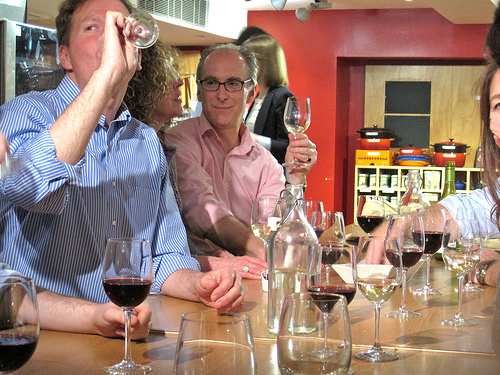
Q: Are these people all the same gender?
A: No, they are both male and female.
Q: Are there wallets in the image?
A: No, there are no wallets.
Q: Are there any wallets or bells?
A: No, there are no wallets or bells.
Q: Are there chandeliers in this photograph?
A: No, there are no chandeliers.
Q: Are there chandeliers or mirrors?
A: No, there are no chandeliers or mirrors.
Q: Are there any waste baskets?
A: No, there are no waste baskets.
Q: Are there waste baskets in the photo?
A: No, there are no waste baskets.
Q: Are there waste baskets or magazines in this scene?
A: No, there are no waste baskets or magazines.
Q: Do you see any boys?
A: No, there are no boys.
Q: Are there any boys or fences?
A: No, there are no boys or fences.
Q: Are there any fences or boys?
A: No, there are no boys or fences.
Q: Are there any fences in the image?
A: No, there are no fences.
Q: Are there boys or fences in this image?
A: No, there are no fences or boys.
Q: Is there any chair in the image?
A: No, there are no chairs.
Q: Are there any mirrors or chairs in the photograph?
A: No, there are no chairs or mirrors.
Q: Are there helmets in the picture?
A: No, there are no helmets.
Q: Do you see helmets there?
A: No, there are no helmets.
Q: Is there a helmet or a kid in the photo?
A: No, there are no helmets or children.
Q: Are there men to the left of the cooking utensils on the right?
A: Yes, there is a man to the left of the cooking utensils.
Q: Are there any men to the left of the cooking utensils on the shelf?
A: Yes, there is a man to the left of the cooking utensils.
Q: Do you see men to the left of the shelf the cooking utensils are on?
A: Yes, there is a man to the left of the shelf.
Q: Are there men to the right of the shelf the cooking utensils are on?
A: No, the man is to the left of the shelf.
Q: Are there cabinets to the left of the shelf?
A: No, there is a man to the left of the shelf.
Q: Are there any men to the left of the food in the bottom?
A: Yes, there is a man to the left of the food.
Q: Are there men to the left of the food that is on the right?
A: Yes, there is a man to the left of the food.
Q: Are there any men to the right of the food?
A: No, the man is to the left of the food.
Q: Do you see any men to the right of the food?
A: No, the man is to the left of the food.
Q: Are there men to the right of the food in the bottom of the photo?
A: No, the man is to the left of the food.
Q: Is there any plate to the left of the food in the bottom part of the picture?
A: No, there is a man to the left of the food.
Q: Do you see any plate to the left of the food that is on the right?
A: No, there is a man to the left of the food.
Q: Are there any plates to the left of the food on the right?
A: No, there is a man to the left of the food.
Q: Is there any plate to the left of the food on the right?
A: No, there is a man to the left of the food.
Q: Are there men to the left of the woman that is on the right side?
A: Yes, there is a man to the left of the woman.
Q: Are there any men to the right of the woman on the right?
A: No, the man is to the left of the woman.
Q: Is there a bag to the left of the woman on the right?
A: No, there is a man to the left of the woman.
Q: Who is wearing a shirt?
A: The man is wearing a shirt.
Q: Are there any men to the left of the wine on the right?
A: Yes, there is a man to the left of the wine.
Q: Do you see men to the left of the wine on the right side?
A: Yes, there is a man to the left of the wine.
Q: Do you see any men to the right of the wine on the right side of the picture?
A: No, the man is to the left of the wine.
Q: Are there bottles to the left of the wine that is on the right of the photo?
A: No, there is a man to the left of the wine.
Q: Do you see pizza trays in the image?
A: No, there are no pizza trays.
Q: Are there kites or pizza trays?
A: No, there are no pizza trays or kites.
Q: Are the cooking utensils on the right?
A: Yes, the cooking utensils are on the right of the image.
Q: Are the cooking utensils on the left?
A: No, the cooking utensils are on the right of the image.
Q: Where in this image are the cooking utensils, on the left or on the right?
A: The cooking utensils are on the right of the image.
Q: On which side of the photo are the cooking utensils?
A: The cooking utensils are on the right of the image.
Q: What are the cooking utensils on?
A: The cooking utensils are on the shelf.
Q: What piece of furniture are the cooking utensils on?
A: The cooking utensils are on the shelf.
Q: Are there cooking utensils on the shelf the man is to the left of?
A: Yes, there are cooking utensils on the shelf.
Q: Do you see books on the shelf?
A: No, there are cooking utensils on the shelf.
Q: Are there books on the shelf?
A: No, there are cooking utensils on the shelf.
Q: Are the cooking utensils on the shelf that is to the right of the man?
A: Yes, the cooking utensils are on the shelf.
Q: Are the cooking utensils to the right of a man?
A: Yes, the cooking utensils are to the right of a man.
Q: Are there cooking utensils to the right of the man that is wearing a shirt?
A: Yes, there are cooking utensils to the right of the man.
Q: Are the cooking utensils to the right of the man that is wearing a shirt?
A: Yes, the cooking utensils are to the right of the man.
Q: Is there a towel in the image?
A: No, there are no towels.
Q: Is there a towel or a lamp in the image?
A: No, there are no towels or lamps.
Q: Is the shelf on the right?
A: Yes, the shelf is on the right of the image.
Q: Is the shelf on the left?
A: No, the shelf is on the right of the image.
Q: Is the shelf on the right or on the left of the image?
A: The shelf is on the right of the image.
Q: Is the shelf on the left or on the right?
A: The shelf is on the right of the image.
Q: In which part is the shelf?
A: The shelf is on the right of the image.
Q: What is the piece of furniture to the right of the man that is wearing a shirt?
A: The piece of furniture is a shelf.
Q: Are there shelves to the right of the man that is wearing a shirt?
A: Yes, there is a shelf to the right of the man.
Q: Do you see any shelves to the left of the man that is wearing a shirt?
A: No, the shelf is to the right of the man.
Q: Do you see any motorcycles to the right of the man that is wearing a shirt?
A: No, there is a shelf to the right of the man.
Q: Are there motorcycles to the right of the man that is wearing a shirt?
A: No, there is a shelf to the right of the man.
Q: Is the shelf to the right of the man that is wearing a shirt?
A: Yes, the shelf is to the right of the man.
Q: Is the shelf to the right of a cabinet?
A: No, the shelf is to the right of the man.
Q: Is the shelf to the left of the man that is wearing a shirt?
A: No, the shelf is to the right of the man.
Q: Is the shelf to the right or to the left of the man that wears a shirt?
A: The shelf is to the right of the man.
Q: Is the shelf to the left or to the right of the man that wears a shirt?
A: The shelf is to the right of the man.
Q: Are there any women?
A: Yes, there is a woman.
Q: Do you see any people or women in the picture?
A: Yes, there is a woman.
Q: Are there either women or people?
A: Yes, there is a woman.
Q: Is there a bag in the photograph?
A: No, there are no bags.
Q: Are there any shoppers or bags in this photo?
A: No, there are no bags or shoppers.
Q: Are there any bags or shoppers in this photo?
A: No, there are no bags or shoppers.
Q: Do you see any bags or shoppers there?
A: No, there are no bags or shoppers.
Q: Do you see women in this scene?
A: Yes, there is a woman.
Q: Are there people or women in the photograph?
A: Yes, there is a woman.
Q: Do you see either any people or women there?
A: Yes, there is a woman.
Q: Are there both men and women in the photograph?
A: Yes, there are both a woman and a man.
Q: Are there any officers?
A: No, there are no officers.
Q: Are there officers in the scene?
A: No, there are no officers.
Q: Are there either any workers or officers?
A: No, there are no officers or workers.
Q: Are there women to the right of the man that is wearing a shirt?
A: Yes, there is a woman to the right of the man.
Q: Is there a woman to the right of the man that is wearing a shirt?
A: Yes, there is a woman to the right of the man.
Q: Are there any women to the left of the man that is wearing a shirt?
A: No, the woman is to the right of the man.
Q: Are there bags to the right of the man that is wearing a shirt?
A: No, there is a woman to the right of the man.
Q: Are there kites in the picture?
A: No, there are no kites.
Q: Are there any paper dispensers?
A: No, there are no paper dispensers.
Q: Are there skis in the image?
A: No, there are no skis.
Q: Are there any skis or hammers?
A: No, there are no skis or hammers.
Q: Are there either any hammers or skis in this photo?
A: No, there are no skis or hammers.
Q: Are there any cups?
A: Yes, there is a cup.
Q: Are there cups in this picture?
A: Yes, there is a cup.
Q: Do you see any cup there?
A: Yes, there is a cup.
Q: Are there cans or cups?
A: Yes, there is a cup.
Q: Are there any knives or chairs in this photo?
A: No, there are no chairs or knives.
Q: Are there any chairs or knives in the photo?
A: No, there are no chairs or knives.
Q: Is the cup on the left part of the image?
A: Yes, the cup is on the left of the image.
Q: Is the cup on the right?
A: No, the cup is on the left of the image.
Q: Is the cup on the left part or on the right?
A: The cup is on the left of the image.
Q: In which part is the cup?
A: The cup is on the left of the image.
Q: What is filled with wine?
A: The cup is filled with wine.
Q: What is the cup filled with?
A: The cup is filled with wine.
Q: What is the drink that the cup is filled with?
A: The drink is wine.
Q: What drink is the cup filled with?
A: The cup is filled with wine.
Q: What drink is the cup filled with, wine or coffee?
A: The cup is filled with wine.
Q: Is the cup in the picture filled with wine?
A: Yes, the cup is filled with wine.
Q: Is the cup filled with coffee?
A: No, the cup is filled with wine.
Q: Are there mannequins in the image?
A: No, there are no mannequins.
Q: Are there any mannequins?
A: No, there are no mannequins.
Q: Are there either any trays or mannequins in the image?
A: No, there are no mannequins or trays.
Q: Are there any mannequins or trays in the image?
A: No, there are no mannequins or trays.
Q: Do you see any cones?
A: No, there are no cones.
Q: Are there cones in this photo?
A: No, there are no cones.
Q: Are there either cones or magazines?
A: No, there are no cones or magazines.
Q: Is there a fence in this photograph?
A: No, there are no fences.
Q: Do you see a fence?
A: No, there are no fences.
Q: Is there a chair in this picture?
A: No, there are no chairs.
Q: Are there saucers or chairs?
A: No, there are no chairs or saucers.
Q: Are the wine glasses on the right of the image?
A: Yes, the wine glasses are on the right of the image.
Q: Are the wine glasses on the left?
A: No, the wine glasses are on the right of the image.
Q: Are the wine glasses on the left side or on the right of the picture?
A: The wine glasses are on the right of the image.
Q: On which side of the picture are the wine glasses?
A: The wine glasses are on the right of the image.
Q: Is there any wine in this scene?
A: Yes, there is wine.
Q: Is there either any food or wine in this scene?
A: Yes, there is wine.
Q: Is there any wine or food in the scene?
A: Yes, there is wine.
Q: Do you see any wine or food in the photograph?
A: Yes, there is wine.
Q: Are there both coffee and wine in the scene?
A: No, there is wine but no coffee.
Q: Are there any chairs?
A: No, there are no chairs.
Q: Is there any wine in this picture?
A: Yes, there is wine.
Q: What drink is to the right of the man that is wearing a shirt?
A: The drink is wine.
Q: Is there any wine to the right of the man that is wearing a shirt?
A: Yes, there is wine to the right of the man.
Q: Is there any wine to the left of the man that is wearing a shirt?
A: No, the wine is to the right of the man.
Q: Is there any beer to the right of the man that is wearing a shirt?
A: No, there is wine to the right of the man.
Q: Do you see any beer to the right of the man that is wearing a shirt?
A: No, there is wine to the right of the man.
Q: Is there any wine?
A: Yes, there is wine.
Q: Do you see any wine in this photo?
A: Yes, there is wine.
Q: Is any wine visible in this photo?
A: Yes, there is wine.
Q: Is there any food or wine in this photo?
A: Yes, there is wine.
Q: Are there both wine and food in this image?
A: Yes, there are both wine and food.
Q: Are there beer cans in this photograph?
A: No, there are no beer cans.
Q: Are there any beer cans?
A: No, there are no beer cans.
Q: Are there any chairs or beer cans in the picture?
A: No, there are no beer cans or chairs.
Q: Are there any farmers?
A: No, there are no farmers.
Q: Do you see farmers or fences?
A: No, there are no farmers or fences.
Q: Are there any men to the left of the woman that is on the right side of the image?
A: Yes, there is a man to the left of the woman.